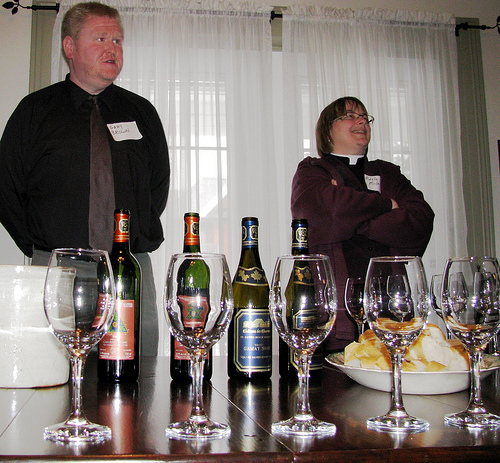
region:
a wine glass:
[23, 245, 149, 448]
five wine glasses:
[26, 237, 496, 436]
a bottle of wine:
[89, 201, 146, 403]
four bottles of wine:
[68, 182, 373, 419]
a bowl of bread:
[333, 274, 498, 399]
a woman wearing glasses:
[289, 70, 420, 225]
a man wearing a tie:
[31, 6, 144, 288]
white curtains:
[29, 2, 499, 266]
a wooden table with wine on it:
[16, 243, 482, 458]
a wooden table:
[29, 267, 468, 461]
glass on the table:
[261, 243, 359, 355]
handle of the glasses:
[31, 356, 492, 433]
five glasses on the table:
[34, 260, 494, 351]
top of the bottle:
[229, 205, 279, 247]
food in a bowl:
[420, 320, 451, 374]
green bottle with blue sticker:
[228, 204, 275, 384]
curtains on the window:
[179, 52, 306, 138]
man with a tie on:
[18, 3, 156, 192]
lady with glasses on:
[293, 76, 430, 194]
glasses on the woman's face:
[336, 112, 390, 127]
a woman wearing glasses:
[299, 80, 423, 161]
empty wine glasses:
[57, 252, 492, 386]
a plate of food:
[322, 307, 492, 391]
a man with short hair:
[22, 9, 141, 93]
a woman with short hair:
[288, 95, 383, 164]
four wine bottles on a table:
[51, 210, 329, 392]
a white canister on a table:
[0, 257, 80, 372]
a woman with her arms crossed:
[275, 96, 446, 266]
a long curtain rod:
[0, 0, 488, 16]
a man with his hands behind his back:
[8, 27, 161, 262]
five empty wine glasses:
[0, 250, 497, 410]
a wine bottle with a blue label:
[212, 198, 270, 397]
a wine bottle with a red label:
[95, 204, 137, 405]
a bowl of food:
[327, 327, 496, 389]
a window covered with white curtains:
[65, 15, 468, 117]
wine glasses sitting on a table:
[82, 255, 499, 461]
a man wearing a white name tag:
[34, 12, 166, 191]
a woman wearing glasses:
[284, 77, 444, 370]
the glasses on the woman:
[324, 106, 383, 129]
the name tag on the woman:
[355, 165, 396, 195]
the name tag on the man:
[101, 111, 161, 150]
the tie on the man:
[84, 88, 109, 268]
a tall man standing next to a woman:
[1, 3, 181, 350]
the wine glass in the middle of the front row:
[263, 235, 348, 444]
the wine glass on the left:
[31, 233, 126, 457]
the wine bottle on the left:
[91, 191, 164, 390]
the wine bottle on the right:
[273, 198, 334, 392]